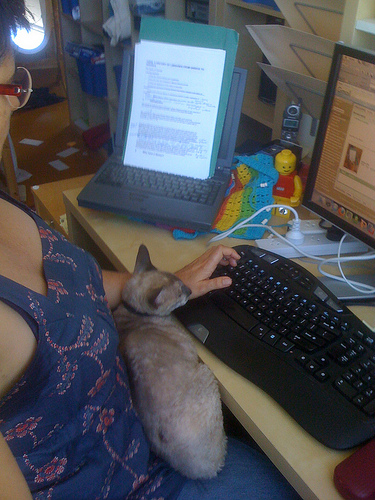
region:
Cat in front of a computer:
[122, 272, 191, 489]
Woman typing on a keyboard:
[187, 241, 260, 335]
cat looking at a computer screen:
[133, 249, 176, 313]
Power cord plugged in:
[276, 200, 314, 256]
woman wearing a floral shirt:
[35, 301, 122, 467]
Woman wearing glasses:
[5, 55, 39, 110]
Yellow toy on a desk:
[270, 138, 298, 211]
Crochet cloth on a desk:
[234, 155, 268, 233]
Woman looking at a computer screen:
[331, 69, 369, 258]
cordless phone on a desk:
[274, 99, 309, 161]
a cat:
[123, 265, 209, 406]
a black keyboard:
[249, 290, 350, 386]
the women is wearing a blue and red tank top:
[44, 360, 133, 479]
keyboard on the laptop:
[80, 163, 218, 226]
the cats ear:
[154, 286, 170, 307]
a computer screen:
[318, 149, 371, 207]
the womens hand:
[180, 246, 237, 292]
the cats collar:
[126, 300, 138, 314]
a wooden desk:
[259, 416, 284, 456]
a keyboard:
[114, 169, 192, 200]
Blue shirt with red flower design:
[16, 386, 133, 493]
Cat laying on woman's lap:
[121, 243, 207, 443]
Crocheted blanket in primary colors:
[220, 157, 271, 230]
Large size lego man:
[265, 148, 305, 219]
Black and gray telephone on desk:
[273, 98, 304, 149]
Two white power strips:
[285, 219, 335, 253]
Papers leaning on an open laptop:
[118, 24, 238, 178]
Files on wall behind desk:
[276, 6, 338, 108]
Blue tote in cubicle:
[66, 44, 106, 101]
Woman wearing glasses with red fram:
[1, 10, 31, 146]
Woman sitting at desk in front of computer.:
[6, 189, 288, 495]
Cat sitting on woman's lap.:
[105, 234, 243, 482]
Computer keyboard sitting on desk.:
[170, 221, 370, 454]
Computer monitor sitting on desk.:
[298, 39, 370, 251]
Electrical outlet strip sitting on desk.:
[259, 212, 366, 267]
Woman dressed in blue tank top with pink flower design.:
[1, 189, 183, 498]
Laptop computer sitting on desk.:
[70, 45, 249, 231]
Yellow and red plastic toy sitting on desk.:
[267, 146, 303, 205]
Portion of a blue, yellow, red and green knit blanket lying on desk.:
[210, 147, 281, 239]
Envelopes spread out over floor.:
[16, 133, 81, 174]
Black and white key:
[332, 373, 356, 399]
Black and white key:
[315, 368, 329, 383]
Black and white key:
[287, 350, 312, 362]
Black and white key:
[319, 319, 343, 341]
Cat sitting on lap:
[112, 236, 219, 497]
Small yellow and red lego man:
[269, 141, 304, 242]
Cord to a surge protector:
[208, 208, 371, 303]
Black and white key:
[251, 320, 267, 338]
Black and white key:
[303, 320, 344, 349]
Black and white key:
[247, 276, 310, 342]